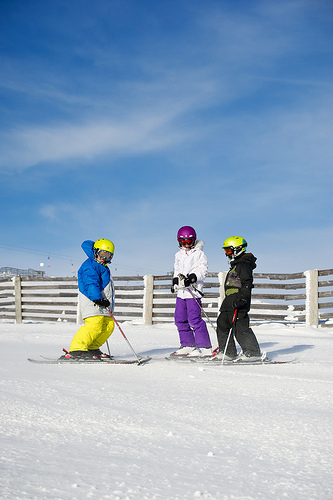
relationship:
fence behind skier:
[0, 267, 332, 327] [208, 235, 266, 362]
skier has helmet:
[208, 235, 266, 362] [222, 236, 249, 257]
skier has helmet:
[168, 225, 215, 359] [176, 225, 198, 243]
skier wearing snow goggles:
[58, 237, 116, 361] [95, 248, 114, 264]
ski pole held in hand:
[105, 304, 142, 364] [96, 300, 110, 309]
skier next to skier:
[208, 235, 266, 362] [168, 225, 215, 359]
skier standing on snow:
[208, 235, 266, 362] [1, 322, 333, 499]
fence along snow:
[0, 267, 332, 327] [1, 322, 333, 499]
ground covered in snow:
[1, 321, 333, 499] [1, 322, 333, 499]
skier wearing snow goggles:
[208, 235, 266, 362] [223, 246, 235, 257]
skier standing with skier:
[168, 225, 215, 359] [58, 237, 116, 361]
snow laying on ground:
[1, 322, 333, 499] [1, 321, 333, 499]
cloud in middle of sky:
[0, 93, 207, 172] [0, 0, 332, 315]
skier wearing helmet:
[168, 225, 215, 359] [176, 225, 198, 243]